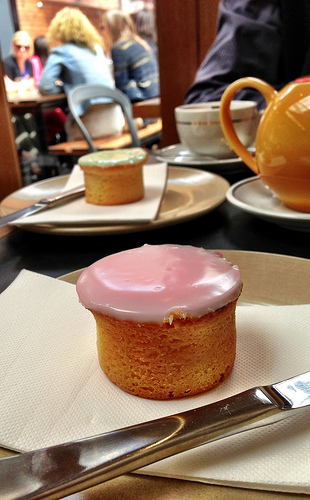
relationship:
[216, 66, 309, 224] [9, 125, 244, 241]
kettle on plate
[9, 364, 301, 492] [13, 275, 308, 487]
knife on napkin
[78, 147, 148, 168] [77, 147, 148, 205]
frosting on cupcake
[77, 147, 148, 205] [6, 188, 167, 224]
cupcake on napkin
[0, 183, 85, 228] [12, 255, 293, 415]
butterknife next to napkin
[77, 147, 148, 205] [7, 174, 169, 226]
cupcake on napkin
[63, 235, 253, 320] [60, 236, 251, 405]
icing on cupcake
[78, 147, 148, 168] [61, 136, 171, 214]
frosting on cupcake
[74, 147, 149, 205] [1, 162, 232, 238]
cupcake on plate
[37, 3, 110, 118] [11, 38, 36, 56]
person wearing glasses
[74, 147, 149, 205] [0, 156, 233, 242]
cupcake on plate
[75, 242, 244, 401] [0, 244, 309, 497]
cupcake on plate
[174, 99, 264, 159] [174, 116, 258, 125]
cup with gold line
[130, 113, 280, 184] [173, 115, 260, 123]
saucer with gold line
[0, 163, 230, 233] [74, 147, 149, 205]
plate holding cupcake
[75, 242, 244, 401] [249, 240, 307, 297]
cupcake on plate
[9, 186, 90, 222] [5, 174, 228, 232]
butterknife on plate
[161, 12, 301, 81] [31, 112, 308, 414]
person at tabble